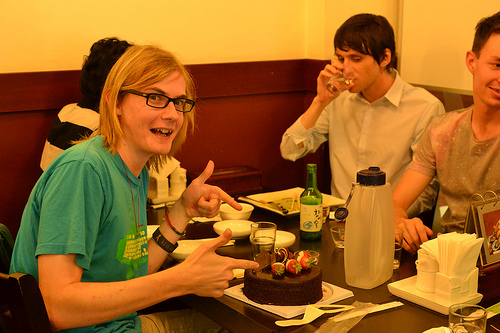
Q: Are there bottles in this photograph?
A: Yes, there is a bottle.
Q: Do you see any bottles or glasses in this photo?
A: Yes, there is a bottle.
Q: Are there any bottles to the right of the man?
A: Yes, there is a bottle to the right of the man.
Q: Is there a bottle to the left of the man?
A: No, the bottle is to the right of the man.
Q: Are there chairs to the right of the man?
A: No, there is a bottle to the right of the man.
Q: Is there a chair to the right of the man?
A: No, there is a bottle to the right of the man.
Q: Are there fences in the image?
A: No, there are no fences.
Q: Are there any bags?
A: No, there are no bags.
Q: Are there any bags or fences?
A: No, there are no bags or fences.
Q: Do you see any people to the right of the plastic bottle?
A: Yes, there is a person to the right of the bottle.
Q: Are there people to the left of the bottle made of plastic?
A: No, the person is to the right of the bottle.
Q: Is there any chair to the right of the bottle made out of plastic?
A: No, there is a person to the right of the bottle.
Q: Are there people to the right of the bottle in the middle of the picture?
A: Yes, there is a person to the right of the bottle.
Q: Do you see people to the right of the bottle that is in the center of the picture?
A: Yes, there is a person to the right of the bottle.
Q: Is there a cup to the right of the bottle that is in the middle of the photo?
A: No, there is a person to the right of the bottle.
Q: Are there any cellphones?
A: No, there are no cellphones.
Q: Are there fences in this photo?
A: No, there are no fences.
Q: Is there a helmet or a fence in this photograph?
A: No, there are no fences or helmets.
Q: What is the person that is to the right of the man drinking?
A: The person is drinking water.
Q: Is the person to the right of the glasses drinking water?
A: Yes, the person is drinking water.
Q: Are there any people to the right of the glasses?
A: Yes, there is a person to the right of the glasses.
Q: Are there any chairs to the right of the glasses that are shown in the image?
A: No, there is a person to the right of the glasses.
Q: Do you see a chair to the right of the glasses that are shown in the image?
A: No, there is a person to the right of the glasses.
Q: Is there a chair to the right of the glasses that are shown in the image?
A: No, there is a person to the right of the glasses.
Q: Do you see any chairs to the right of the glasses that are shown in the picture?
A: No, there is a person to the right of the glasses.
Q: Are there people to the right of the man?
A: Yes, there is a person to the right of the man.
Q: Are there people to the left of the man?
A: No, the person is to the right of the man.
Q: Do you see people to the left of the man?
A: No, the person is to the right of the man.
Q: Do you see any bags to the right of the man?
A: No, there is a person to the right of the man.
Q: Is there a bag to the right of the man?
A: No, there is a person to the right of the man.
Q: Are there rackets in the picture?
A: No, there are no rackets.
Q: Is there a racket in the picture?
A: No, there are no rackets.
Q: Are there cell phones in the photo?
A: No, there are no cell phones.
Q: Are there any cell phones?
A: No, there are no cell phones.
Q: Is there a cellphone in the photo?
A: No, there are no cell phones.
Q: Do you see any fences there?
A: No, there are no fences.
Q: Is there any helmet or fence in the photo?
A: No, there are no fences or helmets.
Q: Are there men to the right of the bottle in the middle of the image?
A: No, the man is to the left of the bottle.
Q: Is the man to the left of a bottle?
A: Yes, the man is to the left of a bottle.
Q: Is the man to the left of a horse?
A: No, the man is to the left of a bottle.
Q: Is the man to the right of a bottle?
A: No, the man is to the left of a bottle.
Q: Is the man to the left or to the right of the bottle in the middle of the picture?
A: The man is to the left of the bottle.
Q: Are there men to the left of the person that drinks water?
A: Yes, there is a man to the left of the person.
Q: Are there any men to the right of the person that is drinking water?
A: No, the man is to the left of the person.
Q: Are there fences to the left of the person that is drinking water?
A: No, there is a man to the left of the person.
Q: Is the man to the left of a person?
A: Yes, the man is to the left of a person.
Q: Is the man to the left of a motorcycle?
A: No, the man is to the left of a person.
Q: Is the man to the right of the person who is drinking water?
A: No, the man is to the left of the person.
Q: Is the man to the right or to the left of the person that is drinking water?
A: The man is to the left of the person.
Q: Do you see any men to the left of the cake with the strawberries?
A: Yes, there is a man to the left of the cake.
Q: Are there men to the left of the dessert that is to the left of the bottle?
A: Yes, there is a man to the left of the cake.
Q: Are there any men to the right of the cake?
A: No, the man is to the left of the cake.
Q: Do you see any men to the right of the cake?
A: No, the man is to the left of the cake.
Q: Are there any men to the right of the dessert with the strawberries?
A: No, the man is to the left of the cake.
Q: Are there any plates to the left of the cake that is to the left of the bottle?
A: No, there is a man to the left of the cake.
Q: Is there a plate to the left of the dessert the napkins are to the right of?
A: No, there is a man to the left of the cake.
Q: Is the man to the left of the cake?
A: Yes, the man is to the left of the cake.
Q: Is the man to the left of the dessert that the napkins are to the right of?
A: Yes, the man is to the left of the cake.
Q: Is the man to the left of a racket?
A: No, the man is to the left of the cake.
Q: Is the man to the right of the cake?
A: No, the man is to the left of the cake.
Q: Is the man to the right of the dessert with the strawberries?
A: No, the man is to the left of the cake.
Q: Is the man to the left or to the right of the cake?
A: The man is to the left of the cake.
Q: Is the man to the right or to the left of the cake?
A: The man is to the left of the cake.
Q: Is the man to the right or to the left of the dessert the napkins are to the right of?
A: The man is to the left of the cake.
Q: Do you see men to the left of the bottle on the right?
A: Yes, there is a man to the left of the bottle.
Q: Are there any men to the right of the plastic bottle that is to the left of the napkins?
A: No, the man is to the left of the bottle.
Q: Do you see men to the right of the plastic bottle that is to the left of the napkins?
A: No, the man is to the left of the bottle.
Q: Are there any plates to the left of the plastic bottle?
A: No, there is a man to the left of the bottle.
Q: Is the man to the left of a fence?
A: No, the man is to the left of a bottle.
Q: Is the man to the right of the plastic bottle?
A: No, the man is to the left of the bottle.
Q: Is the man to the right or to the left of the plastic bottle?
A: The man is to the left of the bottle.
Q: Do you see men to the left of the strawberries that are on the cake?
A: Yes, there is a man to the left of the strawberries.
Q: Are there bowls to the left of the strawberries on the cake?
A: No, there is a man to the left of the strawberries.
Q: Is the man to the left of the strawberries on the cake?
A: Yes, the man is to the left of the strawberries.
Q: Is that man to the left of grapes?
A: No, the man is to the left of the strawberries.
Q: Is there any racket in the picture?
A: No, there are no rackets.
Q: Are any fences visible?
A: No, there are no fences.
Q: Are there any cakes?
A: Yes, there is a cake.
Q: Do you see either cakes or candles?
A: Yes, there is a cake.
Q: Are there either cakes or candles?
A: Yes, there is a cake.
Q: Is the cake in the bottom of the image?
A: Yes, the cake is in the bottom of the image.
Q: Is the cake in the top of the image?
A: No, the cake is in the bottom of the image.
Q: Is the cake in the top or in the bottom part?
A: The cake is in the bottom of the image.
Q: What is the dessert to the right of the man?
A: The dessert is a cake.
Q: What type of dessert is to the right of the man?
A: The dessert is a cake.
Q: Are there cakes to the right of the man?
A: Yes, there is a cake to the right of the man.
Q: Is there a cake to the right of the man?
A: Yes, there is a cake to the right of the man.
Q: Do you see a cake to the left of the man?
A: No, the cake is to the right of the man.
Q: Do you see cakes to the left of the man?
A: No, the cake is to the right of the man.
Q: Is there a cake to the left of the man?
A: No, the cake is to the right of the man.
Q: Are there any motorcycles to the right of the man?
A: No, there is a cake to the right of the man.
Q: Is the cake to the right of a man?
A: Yes, the cake is to the right of a man.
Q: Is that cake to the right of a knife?
A: No, the cake is to the right of a man.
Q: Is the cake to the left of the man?
A: No, the cake is to the right of the man.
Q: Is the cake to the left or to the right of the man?
A: The cake is to the right of the man.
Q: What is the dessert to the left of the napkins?
A: The dessert is a cake.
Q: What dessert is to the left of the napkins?
A: The dessert is a cake.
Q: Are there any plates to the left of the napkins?
A: No, there is a cake to the left of the napkins.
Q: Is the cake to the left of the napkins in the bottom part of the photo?
A: Yes, the cake is to the left of the napkins.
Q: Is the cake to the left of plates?
A: No, the cake is to the left of the napkins.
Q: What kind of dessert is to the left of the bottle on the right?
A: The dessert is a cake.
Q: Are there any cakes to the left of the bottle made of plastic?
A: Yes, there is a cake to the left of the bottle.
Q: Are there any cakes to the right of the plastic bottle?
A: No, the cake is to the left of the bottle.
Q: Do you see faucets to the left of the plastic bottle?
A: No, there is a cake to the left of the bottle.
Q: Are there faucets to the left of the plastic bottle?
A: No, there is a cake to the left of the bottle.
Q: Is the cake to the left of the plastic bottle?
A: Yes, the cake is to the left of the bottle.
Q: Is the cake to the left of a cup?
A: No, the cake is to the left of the bottle.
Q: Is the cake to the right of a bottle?
A: No, the cake is to the left of a bottle.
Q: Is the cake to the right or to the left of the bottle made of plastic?
A: The cake is to the left of the bottle.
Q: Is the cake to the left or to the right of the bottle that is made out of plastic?
A: The cake is to the left of the bottle.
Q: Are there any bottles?
A: Yes, there is a bottle.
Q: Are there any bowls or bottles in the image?
A: Yes, there is a bottle.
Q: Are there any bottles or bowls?
A: Yes, there is a bottle.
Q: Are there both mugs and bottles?
A: No, there is a bottle but no mugs.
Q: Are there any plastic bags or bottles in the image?
A: Yes, there is a plastic bottle.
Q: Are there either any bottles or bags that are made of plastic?
A: Yes, the bottle is made of plastic.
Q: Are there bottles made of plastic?
A: Yes, there is a bottle that is made of plastic.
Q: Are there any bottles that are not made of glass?
A: Yes, there is a bottle that is made of plastic.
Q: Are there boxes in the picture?
A: No, there are no boxes.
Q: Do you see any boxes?
A: No, there are no boxes.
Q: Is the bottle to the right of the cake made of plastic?
A: Yes, the bottle is made of plastic.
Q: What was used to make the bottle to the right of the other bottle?
A: The bottle is made of plastic.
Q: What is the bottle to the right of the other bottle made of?
A: The bottle is made of plastic.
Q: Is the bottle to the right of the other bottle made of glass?
A: No, the bottle is made of plastic.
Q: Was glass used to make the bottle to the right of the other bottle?
A: No, the bottle is made of plastic.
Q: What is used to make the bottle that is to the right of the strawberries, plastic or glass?
A: The bottle is made of plastic.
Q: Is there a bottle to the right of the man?
A: Yes, there is a bottle to the right of the man.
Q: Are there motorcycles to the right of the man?
A: No, there is a bottle to the right of the man.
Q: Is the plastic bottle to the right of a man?
A: Yes, the bottle is to the right of a man.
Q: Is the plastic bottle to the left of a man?
A: No, the bottle is to the right of a man.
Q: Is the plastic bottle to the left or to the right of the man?
A: The bottle is to the right of the man.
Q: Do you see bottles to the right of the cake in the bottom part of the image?
A: Yes, there is a bottle to the right of the cake.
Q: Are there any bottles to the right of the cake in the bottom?
A: Yes, there is a bottle to the right of the cake.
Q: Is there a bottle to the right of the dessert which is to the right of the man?
A: Yes, there is a bottle to the right of the cake.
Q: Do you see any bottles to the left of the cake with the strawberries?
A: No, the bottle is to the right of the cake.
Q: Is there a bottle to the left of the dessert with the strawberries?
A: No, the bottle is to the right of the cake.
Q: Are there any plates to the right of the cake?
A: No, there is a bottle to the right of the cake.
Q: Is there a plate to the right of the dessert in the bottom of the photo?
A: No, there is a bottle to the right of the cake.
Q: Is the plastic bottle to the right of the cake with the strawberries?
A: Yes, the bottle is to the right of the cake.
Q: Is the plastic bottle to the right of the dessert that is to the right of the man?
A: Yes, the bottle is to the right of the cake.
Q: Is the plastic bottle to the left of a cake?
A: No, the bottle is to the right of a cake.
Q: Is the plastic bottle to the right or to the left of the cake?
A: The bottle is to the right of the cake.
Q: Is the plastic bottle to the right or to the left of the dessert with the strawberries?
A: The bottle is to the right of the cake.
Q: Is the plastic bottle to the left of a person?
A: Yes, the bottle is to the left of a person.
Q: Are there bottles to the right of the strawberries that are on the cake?
A: Yes, there is a bottle to the right of the strawberries.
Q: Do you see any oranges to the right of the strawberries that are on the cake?
A: No, there is a bottle to the right of the strawberries.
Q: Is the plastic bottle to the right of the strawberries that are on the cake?
A: Yes, the bottle is to the right of the strawberries.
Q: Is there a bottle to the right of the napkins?
A: No, the bottle is to the left of the napkins.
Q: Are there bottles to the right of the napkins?
A: No, the bottle is to the left of the napkins.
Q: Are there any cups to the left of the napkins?
A: No, there is a bottle to the left of the napkins.